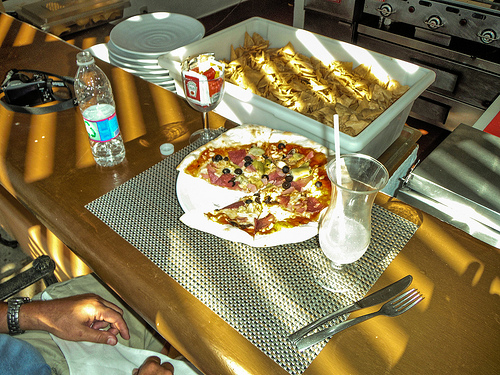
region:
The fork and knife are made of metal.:
[266, 265, 428, 355]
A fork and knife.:
[266, 269, 434, 356]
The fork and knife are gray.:
[278, 268, 421, 357]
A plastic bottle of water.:
[60, 40, 132, 173]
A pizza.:
[171, 119, 346, 264]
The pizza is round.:
[159, 120, 348, 248]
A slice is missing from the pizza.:
[169, 122, 350, 242]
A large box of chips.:
[167, 12, 437, 157]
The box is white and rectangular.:
[157, 10, 442, 160]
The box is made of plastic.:
[153, 17, 440, 173]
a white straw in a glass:
[332, 113, 345, 186]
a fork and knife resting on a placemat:
[288, 270, 429, 356]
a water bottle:
[65, 46, 126, 172]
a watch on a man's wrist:
[5, 291, 30, 344]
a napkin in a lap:
[38, 284, 205, 374]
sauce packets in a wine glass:
[183, 55, 220, 145]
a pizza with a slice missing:
[173, 121, 340, 241]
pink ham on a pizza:
[229, 142, 243, 163]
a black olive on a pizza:
[280, 164, 290, 173]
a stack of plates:
[103, 8, 206, 102]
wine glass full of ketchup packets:
[171, 55, 236, 155]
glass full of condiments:
[176, 50, 233, 154]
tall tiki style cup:
[307, 142, 391, 287]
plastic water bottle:
[58, 46, 140, 179]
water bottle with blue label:
[61, 46, 142, 178]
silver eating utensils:
[283, 265, 423, 355]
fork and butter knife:
[286, 268, 427, 350]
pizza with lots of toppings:
[168, 112, 348, 255]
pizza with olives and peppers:
[168, 109, 347, 251]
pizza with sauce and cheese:
[172, 115, 345, 255]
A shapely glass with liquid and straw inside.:
[314, 154, 389, 292]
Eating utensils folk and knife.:
[284, 273, 425, 348]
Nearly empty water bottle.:
[73, 48, 124, 168]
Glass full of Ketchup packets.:
[179, 53, 224, 150]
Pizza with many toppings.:
[175, 122, 328, 243]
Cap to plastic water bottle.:
[157, 142, 176, 155]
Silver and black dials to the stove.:
[375, 4, 499, 48]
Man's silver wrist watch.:
[7, 294, 29, 335]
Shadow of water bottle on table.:
[125, 112, 197, 152]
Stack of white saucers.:
[107, 9, 207, 90]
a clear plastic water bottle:
[66, 48, 127, 170]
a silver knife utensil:
[280, 273, 414, 347]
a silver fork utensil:
[292, 286, 424, 356]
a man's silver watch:
[3, 295, 33, 335]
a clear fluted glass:
[314, 149, 382, 294]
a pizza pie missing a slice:
[175, 125, 336, 241]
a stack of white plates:
[105, 9, 196, 89]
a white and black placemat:
[82, 132, 414, 374]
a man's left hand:
[5, 294, 128, 347]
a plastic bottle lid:
[156, 141, 176, 157]